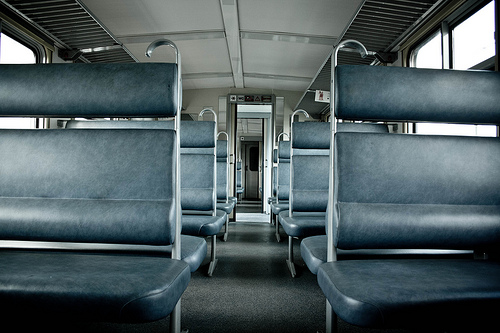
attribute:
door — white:
[239, 139, 267, 203]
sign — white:
[314, 89, 329, 104]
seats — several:
[13, 39, 495, 325]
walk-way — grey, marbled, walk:
[183, 198, 320, 331]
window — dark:
[8, 26, 65, 195]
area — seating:
[6, 141, 498, 312]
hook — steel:
[146, 31, 183, 66]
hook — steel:
[323, 32, 373, 64]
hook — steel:
[198, 100, 221, 121]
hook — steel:
[289, 103, 313, 123]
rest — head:
[9, 63, 179, 124]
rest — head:
[340, 66, 495, 133]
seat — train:
[323, 66, 496, 322]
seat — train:
[1, 61, 201, 324]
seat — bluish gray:
[311, 51, 494, 328]